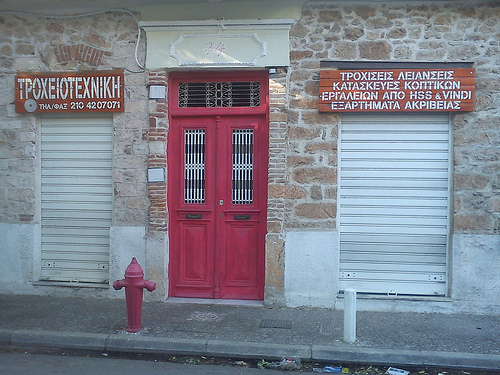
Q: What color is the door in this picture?
A: Red.